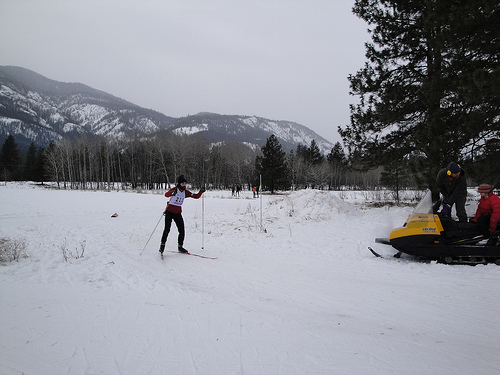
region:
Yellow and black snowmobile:
[364, 196, 489, 276]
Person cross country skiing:
[138, 166, 227, 277]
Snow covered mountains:
[5, 66, 295, 156]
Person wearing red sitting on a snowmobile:
[471, 167, 498, 261]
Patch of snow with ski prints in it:
[92, 276, 417, 373]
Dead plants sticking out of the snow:
[7, 227, 37, 278]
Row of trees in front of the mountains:
[10, 125, 271, 190]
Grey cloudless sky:
[141, 51, 319, 99]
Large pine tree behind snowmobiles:
[343, 44, 492, 267]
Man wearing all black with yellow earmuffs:
[434, 153, 474, 218]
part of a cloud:
[249, 22, 300, 59]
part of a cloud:
[238, 260, 282, 295]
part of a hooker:
[198, 227, 213, 256]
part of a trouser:
[170, 221, 184, 236]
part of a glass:
[426, 201, 446, 215]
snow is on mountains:
[5, 80, 297, 186]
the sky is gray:
[80, 39, 326, 103]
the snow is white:
[43, 310, 492, 372]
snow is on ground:
[66, 271, 431, 371]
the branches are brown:
[0, 239, 134, 284]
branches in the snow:
[6, 231, 130, 324]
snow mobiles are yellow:
[401, 207, 488, 269]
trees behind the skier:
[1, 132, 377, 282]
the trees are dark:
[18, 117, 369, 202]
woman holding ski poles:
[143, 155, 220, 262]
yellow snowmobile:
[362, 191, 494, 269]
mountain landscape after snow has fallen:
[2, 53, 357, 190]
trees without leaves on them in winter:
[7, 125, 392, 206]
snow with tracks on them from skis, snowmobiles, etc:
[45, 261, 357, 371]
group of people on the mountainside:
[222, 181, 267, 202]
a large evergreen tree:
[333, 0, 495, 218]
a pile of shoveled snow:
[269, 186, 368, 232]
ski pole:
[197, 184, 210, 253]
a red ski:
[168, 251, 222, 262]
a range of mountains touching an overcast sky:
[7, 64, 287, 146]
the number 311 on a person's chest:
[169, 192, 189, 202]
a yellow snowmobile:
[387, 210, 491, 260]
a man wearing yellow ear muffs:
[430, 156, 472, 224]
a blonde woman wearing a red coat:
[474, 182, 497, 232]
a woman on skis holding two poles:
[147, 177, 221, 268]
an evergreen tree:
[365, 1, 495, 103]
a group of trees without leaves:
[60, 141, 260, 181]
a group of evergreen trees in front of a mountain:
[2, 141, 49, 184]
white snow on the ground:
[207, 277, 439, 369]